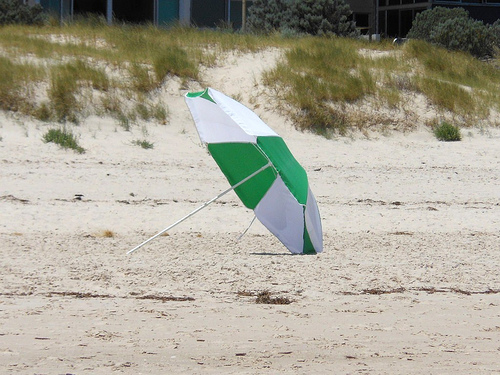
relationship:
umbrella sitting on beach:
[185, 87, 324, 254] [2, 141, 498, 373]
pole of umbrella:
[119, 161, 270, 262] [185, 87, 324, 254]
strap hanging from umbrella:
[236, 215, 255, 245] [185, 87, 324, 254]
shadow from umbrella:
[253, 251, 314, 256] [185, 87, 324, 254]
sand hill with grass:
[1, 23, 500, 145] [0, 22, 500, 154]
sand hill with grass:
[1, 23, 500, 145] [223, 23, 290, 53]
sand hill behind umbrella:
[1, 23, 500, 145] [185, 87, 324, 254]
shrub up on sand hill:
[431, 17, 492, 55] [1, 23, 500, 145]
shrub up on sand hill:
[432, 18, 499, 54] [1, 23, 500, 145]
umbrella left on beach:
[185, 87, 324, 254] [2, 141, 498, 373]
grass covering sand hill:
[0, 22, 500, 154] [1, 23, 500, 145]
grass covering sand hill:
[223, 23, 290, 53] [1, 23, 500, 145]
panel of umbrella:
[209, 142, 276, 207] [185, 87, 324, 254]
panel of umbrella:
[255, 136, 309, 205] [185, 87, 324, 254]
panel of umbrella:
[186, 90, 216, 103] [185, 87, 324, 254]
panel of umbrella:
[302, 207, 317, 255] [185, 87, 324, 254]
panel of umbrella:
[212, 90, 278, 137] [185, 87, 324, 254]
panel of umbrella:
[186, 97, 255, 144] [185, 87, 324, 254]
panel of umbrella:
[255, 175, 305, 252] [185, 87, 324, 254]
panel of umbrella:
[305, 187, 324, 254] [185, 87, 324, 254]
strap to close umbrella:
[236, 215, 255, 245] [185, 87, 324, 254]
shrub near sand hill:
[431, 17, 492, 55] [1, 23, 500, 145]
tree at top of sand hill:
[0, 0, 45, 28] [1, 23, 500, 145]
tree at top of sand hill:
[243, 0, 361, 38] [1, 23, 500, 145]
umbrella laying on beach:
[185, 87, 324, 254] [2, 141, 498, 373]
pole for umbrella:
[119, 161, 270, 262] [185, 87, 324, 254]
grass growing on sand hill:
[0, 22, 500, 154] [1, 23, 500, 145]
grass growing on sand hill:
[223, 23, 290, 53] [1, 23, 500, 145]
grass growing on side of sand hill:
[0, 22, 500, 154] [1, 23, 500, 145]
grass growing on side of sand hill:
[223, 23, 290, 53] [1, 23, 500, 145]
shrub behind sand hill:
[431, 17, 492, 55] [1, 23, 500, 145]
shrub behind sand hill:
[432, 18, 499, 54] [1, 23, 500, 145]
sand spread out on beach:
[1, 128, 499, 374] [2, 141, 498, 373]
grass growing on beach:
[433, 126, 461, 142] [2, 141, 498, 373]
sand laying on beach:
[1, 128, 499, 374] [2, 141, 498, 373]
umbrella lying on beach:
[185, 87, 324, 254] [2, 141, 498, 373]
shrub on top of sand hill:
[431, 17, 492, 55] [1, 23, 500, 145]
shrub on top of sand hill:
[432, 18, 499, 54] [1, 23, 500, 145]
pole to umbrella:
[119, 161, 270, 262] [185, 87, 324, 254]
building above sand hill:
[3, 1, 499, 40] [1, 23, 500, 145]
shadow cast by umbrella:
[253, 251, 314, 256] [185, 87, 324, 254]